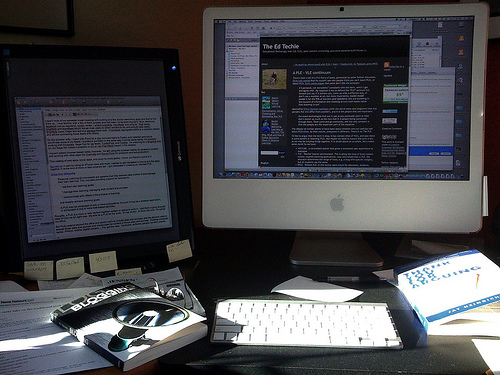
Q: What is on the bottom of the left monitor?
A: Post-it notes.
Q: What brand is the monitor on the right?
A: Apple.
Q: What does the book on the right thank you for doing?
A: Arguing.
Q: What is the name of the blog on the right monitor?
A: The Ed Techie.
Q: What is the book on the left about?
A: Blogging.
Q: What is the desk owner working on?
A: Blogging.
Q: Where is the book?
A: On the desk.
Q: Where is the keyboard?
A: Between the books.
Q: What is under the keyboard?
A: A table.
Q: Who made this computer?
A: Apple.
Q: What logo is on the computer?
A: Apple.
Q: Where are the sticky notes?
A: Left screen.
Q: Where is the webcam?
A: Top of right monitor.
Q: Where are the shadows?
A: On the desk.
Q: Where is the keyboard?
A: In front of the monitor.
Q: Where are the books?
A: On the desk.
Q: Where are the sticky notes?
A: On the monitor.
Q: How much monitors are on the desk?
A: Two.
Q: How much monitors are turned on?
A: Two.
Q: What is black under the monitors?
A: The desk.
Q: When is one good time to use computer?
A: When researching.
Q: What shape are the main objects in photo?
A: Square.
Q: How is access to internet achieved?
A: Modum.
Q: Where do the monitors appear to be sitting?
A: Desk.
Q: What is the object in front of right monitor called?
A: Keyboard.